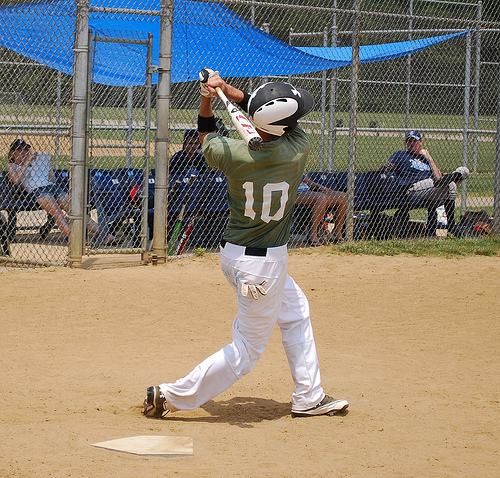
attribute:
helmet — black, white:
[242, 79, 318, 136]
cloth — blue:
[8, 5, 475, 89]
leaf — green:
[487, 59, 497, 71]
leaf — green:
[455, 58, 463, 65]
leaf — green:
[485, 81, 493, 83]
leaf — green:
[482, 98, 492, 114]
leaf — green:
[451, 91, 460, 101]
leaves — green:
[26, 75, 58, 105]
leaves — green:
[439, 49, 458, 69]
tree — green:
[445, 49, 461, 76]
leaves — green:
[435, 61, 447, 78]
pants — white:
[174, 236, 323, 407]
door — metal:
[85, 24, 155, 265]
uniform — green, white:
[201, 122, 310, 433]